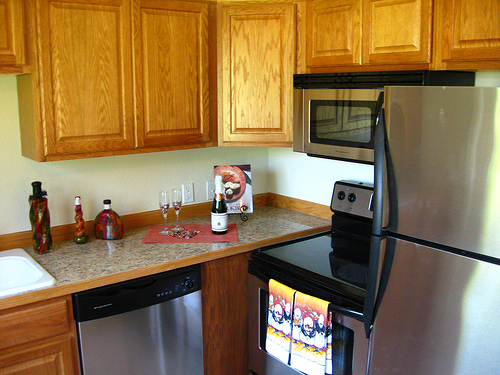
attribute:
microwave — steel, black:
[288, 71, 392, 166]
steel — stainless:
[291, 86, 393, 167]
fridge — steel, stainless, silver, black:
[371, 77, 498, 372]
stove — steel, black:
[240, 175, 367, 369]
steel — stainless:
[243, 279, 370, 373]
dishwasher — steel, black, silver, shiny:
[72, 264, 211, 374]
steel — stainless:
[77, 285, 208, 374]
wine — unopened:
[210, 167, 231, 236]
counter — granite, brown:
[26, 198, 337, 302]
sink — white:
[1, 245, 60, 309]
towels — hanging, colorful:
[264, 274, 339, 374]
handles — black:
[360, 106, 391, 340]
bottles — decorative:
[25, 178, 125, 255]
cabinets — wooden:
[2, 2, 499, 166]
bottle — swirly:
[25, 178, 58, 257]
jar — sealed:
[94, 199, 127, 244]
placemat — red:
[139, 218, 243, 245]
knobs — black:
[330, 191, 360, 210]